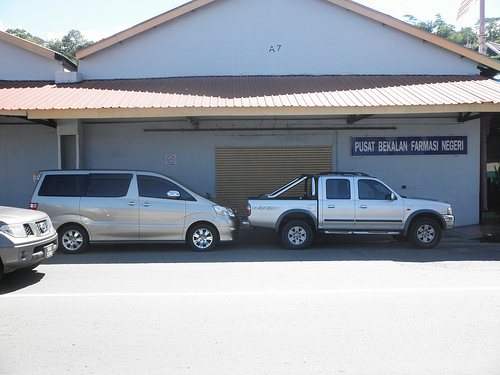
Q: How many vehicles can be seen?
A: Three.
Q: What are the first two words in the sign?
A: Pusat Bekalan.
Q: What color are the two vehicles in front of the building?
A: Silver.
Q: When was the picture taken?
A: During the day.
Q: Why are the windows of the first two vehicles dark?
A: They are tinted.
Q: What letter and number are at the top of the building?
A: A 7.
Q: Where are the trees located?
A: Behind the building.